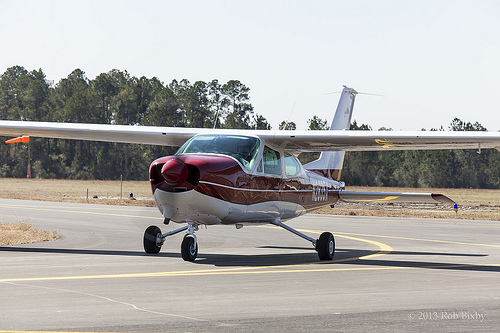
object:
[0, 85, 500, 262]
airplane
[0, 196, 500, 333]
pavement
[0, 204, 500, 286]
stripe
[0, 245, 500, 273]
shadow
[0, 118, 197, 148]
wings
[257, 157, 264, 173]
windows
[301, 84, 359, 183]
tail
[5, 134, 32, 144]
windsock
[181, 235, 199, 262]
front wheel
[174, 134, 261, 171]
cockpit window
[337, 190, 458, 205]
rear wing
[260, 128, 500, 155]
wing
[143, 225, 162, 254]
right wheel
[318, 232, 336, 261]
left wheel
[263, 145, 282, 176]
side windows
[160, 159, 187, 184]
nose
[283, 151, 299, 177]
window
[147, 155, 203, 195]
propeller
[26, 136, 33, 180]
pole